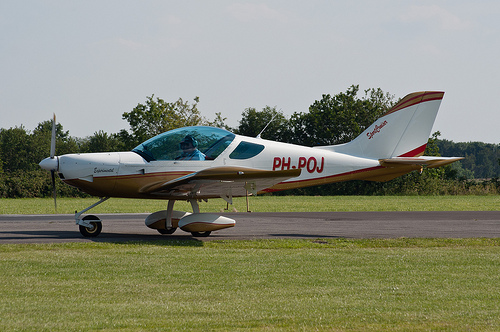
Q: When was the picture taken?
A: Daytime.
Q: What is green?
A: Grass.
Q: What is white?
A: Plane.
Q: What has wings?
A: The plane.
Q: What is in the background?
A: Trees.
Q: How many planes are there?
A: One.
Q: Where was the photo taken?
A: At a airport runway.